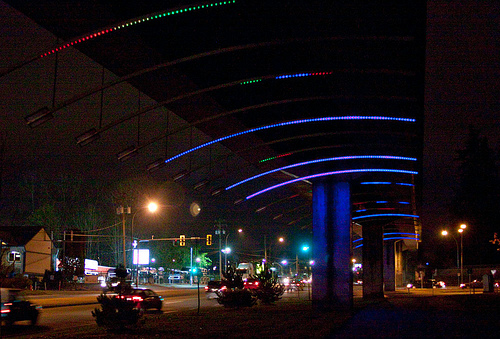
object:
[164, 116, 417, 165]
light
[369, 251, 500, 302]
yard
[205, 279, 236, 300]
car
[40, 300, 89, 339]
street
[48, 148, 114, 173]
night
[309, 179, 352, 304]
pillar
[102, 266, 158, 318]
traffic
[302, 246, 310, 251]
signal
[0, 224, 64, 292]
house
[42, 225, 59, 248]
edge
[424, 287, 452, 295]
part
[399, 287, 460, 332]
path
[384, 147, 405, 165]
part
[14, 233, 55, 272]
part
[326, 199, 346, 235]
part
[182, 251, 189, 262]
part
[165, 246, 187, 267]
bush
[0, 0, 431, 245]
archway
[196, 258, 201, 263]
light